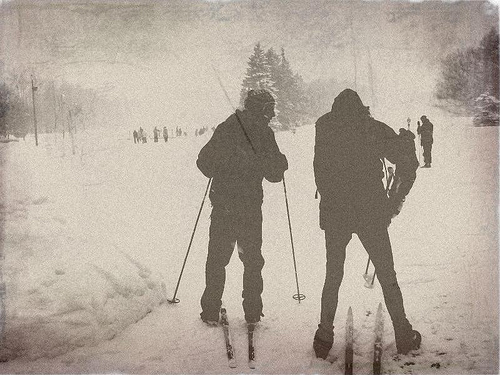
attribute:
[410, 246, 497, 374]
snow — blowing, white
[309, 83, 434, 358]
person — facing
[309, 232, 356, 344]
leg — standing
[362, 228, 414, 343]
leg — standing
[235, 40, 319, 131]
trees — evergreen, pine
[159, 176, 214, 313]
ski pole — metal, black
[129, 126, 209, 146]
people — walking, distant, standing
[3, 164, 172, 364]
snow bank — small, large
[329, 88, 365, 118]
hood — black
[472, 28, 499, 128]
tree — covered